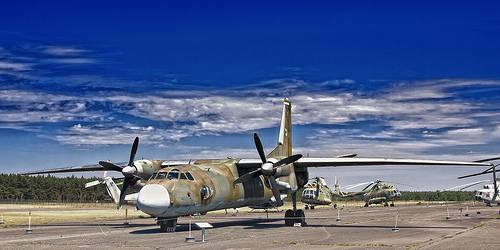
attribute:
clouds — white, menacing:
[133, 88, 277, 133]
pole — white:
[392, 214, 401, 234]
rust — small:
[19, 98, 498, 228]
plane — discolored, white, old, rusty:
[196, 183, 216, 208]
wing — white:
[240, 155, 495, 178]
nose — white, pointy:
[138, 182, 168, 214]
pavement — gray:
[12, 207, 498, 250]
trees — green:
[3, 175, 95, 201]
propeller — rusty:
[99, 137, 150, 209]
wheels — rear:
[284, 207, 304, 226]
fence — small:
[10, 197, 107, 205]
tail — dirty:
[266, 100, 293, 158]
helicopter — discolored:
[307, 175, 338, 207]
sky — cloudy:
[3, 1, 497, 193]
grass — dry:
[6, 205, 136, 225]